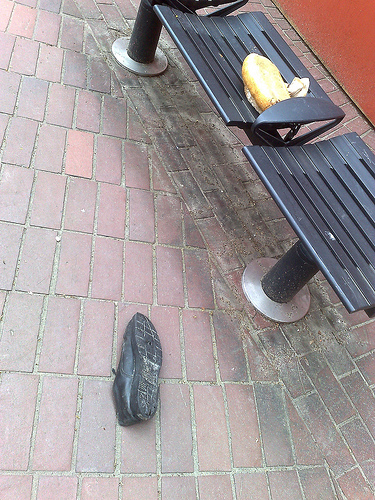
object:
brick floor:
[0, 0, 375, 499]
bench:
[112, 0, 347, 147]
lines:
[57, 175, 77, 236]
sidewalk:
[0, 0, 373, 497]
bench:
[241, 130, 374, 324]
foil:
[242, 85, 261, 113]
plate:
[239, 254, 312, 328]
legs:
[125, 0, 163, 63]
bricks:
[163, 167, 219, 220]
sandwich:
[239, 51, 292, 116]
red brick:
[29, 122, 70, 176]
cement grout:
[1, 464, 322, 476]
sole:
[133, 310, 162, 418]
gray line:
[188, 380, 197, 475]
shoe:
[110, 311, 166, 424]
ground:
[0, 0, 375, 499]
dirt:
[143, 354, 160, 391]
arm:
[253, 94, 346, 140]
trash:
[286, 74, 310, 99]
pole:
[261, 237, 321, 303]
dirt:
[182, 111, 209, 137]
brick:
[189, 379, 234, 474]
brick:
[30, 375, 81, 472]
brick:
[75, 297, 119, 376]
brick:
[86, 235, 124, 299]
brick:
[154, 245, 188, 309]